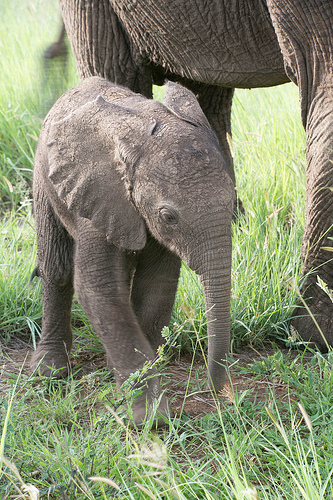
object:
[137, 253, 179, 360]
leg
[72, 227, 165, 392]
leg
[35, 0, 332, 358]
elephant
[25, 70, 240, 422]
elephant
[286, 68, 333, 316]
leg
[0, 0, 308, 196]
grass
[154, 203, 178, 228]
eye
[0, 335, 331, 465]
dirt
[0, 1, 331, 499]
ground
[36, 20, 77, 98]
tail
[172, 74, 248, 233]
leg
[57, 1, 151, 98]
leg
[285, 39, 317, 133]
kin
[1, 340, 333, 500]
grass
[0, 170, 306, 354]
grass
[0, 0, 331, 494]
field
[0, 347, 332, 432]
patch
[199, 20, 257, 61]
skin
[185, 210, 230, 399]
trunk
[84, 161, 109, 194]
skin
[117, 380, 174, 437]
foot